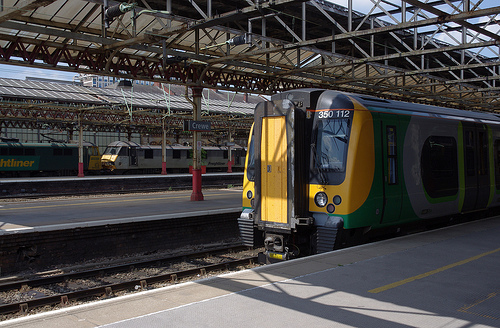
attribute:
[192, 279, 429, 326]
lines — yellow 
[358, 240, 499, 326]
painted lines — orange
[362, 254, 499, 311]
lines — yellow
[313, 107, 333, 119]
number — White 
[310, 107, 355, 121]
numbers — white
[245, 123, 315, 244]
door — yellow 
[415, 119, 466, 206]
window — Large 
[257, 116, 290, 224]
door — yellow 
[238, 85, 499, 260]
train — Green , yellow , black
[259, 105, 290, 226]
door — yellow 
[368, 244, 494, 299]
line — Yellow 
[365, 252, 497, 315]
lines — yellow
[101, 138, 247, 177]
train — black, yellow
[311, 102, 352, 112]
line — red